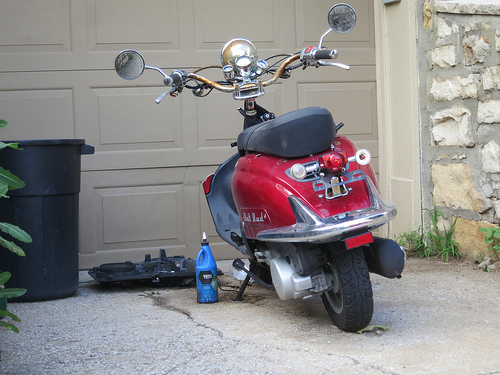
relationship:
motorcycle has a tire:
[114, 2, 407, 332] [320, 241, 373, 332]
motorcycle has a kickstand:
[114, 2, 407, 332] [233, 270, 253, 301]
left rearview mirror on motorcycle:
[114, 49, 145, 81] [114, 2, 407, 332]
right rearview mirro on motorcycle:
[328, 3, 358, 35] [114, 2, 407, 332]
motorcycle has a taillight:
[114, 2, 407, 332] [318, 149, 347, 173]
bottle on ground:
[196, 231, 219, 303] [2, 255, 499, 374]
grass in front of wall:
[400, 207, 460, 262] [416, 2, 500, 271]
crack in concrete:
[143, 288, 390, 374] [0, 258, 499, 371]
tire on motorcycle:
[320, 241, 373, 332] [114, 2, 407, 332]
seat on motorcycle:
[237, 108, 337, 157] [114, 2, 407, 332]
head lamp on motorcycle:
[221, 37, 259, 72] [114, 2, 407, 332]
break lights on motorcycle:
[292, 149, 371, 180] [114, 2, 407, 332]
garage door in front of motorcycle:
[1, 1, 378, 271] [114, 2, 407, 332]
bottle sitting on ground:
[196, 231, 219, 303] [2, 255, 499, 374]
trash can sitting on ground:
[2, 139, 94, 301] [2, 255, 499, 374]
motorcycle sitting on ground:
[114, 2, 407, 332] [2, 255, 499, 374]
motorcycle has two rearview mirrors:
[114, 2, 407, 332] [114, 3, 357, 81]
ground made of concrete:
[2, 255, 499, 374] [0, 258, 499, 371]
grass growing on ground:
[400, 207, 460, 262] [2, 255, 499, 374]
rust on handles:
[187, 52, 300, 92] [186, 53, 301, 93]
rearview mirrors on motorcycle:
[114, 3, 357, 81] [114, 2, 407, 332]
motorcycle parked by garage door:
[114, 2, 407, 332] [1, 1, 378, 271]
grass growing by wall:
[400, 207, 460, 262] [416, 2, 500, 271]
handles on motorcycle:
[186, 53, 301, 93] [114, 2, 407, 332]